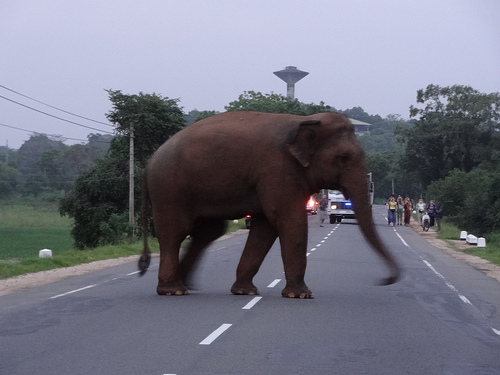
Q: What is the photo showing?
A: It is showing a road.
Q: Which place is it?
A: It is a road.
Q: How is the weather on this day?
A: It is cloudy.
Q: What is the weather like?
A: It is cloudy.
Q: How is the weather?
A: It is cloudy.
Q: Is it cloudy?
A: Yes, it is cloudy.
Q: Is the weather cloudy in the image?
A: Yes, it is cloudy.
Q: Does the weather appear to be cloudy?
A: Yes, it is cloudy.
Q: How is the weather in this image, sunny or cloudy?
A: It is cloudy.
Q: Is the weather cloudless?
A: No, it is cloudy.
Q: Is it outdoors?
A: Yes, it is outdoors.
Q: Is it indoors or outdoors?
A: It is outdoors.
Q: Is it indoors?
A: No, it is outdoors.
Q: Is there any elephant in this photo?
A: Yes, there is an elephant.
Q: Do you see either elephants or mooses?
A: Yes, there is an elephant.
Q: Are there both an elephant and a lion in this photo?
A: No, there is an elephant but no lions.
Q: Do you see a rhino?
A: No, there are no rhinos.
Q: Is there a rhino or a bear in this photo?
A: No, there are no rhinos or bears.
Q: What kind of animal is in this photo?
A: The animal is an elephant.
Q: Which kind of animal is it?
A: The animal is an elephant.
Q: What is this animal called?
A: This is an elephant.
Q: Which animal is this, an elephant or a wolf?
A: This is an elephant.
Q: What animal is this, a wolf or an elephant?
A: This is an elephant.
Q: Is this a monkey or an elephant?
A: This is an elephant.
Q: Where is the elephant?
A: The elephant is on the street.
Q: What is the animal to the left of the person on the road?
A: The animal is an elephant.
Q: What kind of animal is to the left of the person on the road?
A: The animal is an elephant.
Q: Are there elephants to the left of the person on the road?
A: Yes, there is an elephant to the left of the person.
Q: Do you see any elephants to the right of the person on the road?
A: No, the elephant is to the left of the person.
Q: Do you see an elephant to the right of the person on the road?
A: No, the elephant is to the left of the person.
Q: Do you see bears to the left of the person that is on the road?
A: No, there is an elephant to the left of the person.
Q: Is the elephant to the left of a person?
A: Yes, the elephant is to the left of a person.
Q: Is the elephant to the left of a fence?
A: No, the elephant is to the left of a person.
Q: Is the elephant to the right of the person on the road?
A: No, the elephant is to the left of the person.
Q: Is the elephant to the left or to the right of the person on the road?
A: The elephant is to the left of the person.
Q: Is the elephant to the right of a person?
A: No, the elephant is to the left of a person.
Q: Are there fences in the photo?
A: No, there are no fences.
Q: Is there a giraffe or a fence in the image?
A: No, there are no fences or giraffes.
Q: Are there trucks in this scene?
A: Yes, there is a truck.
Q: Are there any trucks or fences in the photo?
A: Yes, there is a truck.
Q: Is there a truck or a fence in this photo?
A: Yes, there is a truck.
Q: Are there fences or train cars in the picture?
A: No, there are no fences or train cars.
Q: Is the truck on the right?
A: Yes, the truck is on the right of the image.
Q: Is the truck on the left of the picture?
A: No, the truck is on the right of the image.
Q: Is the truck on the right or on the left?
A: The truck is on the right of the image.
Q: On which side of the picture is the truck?
A: The truck is on the right of the image.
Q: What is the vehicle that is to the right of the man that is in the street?
A: The vehicle is a truck.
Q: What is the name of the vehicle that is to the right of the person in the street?
A: The vehicle is a truck.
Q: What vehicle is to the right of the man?
A: The vehicle is a truck.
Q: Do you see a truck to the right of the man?
A: Yes, there is a truck to the right of the man.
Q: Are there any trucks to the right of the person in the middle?
A: Yes, there is a truck to the right of the man.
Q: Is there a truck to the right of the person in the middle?
A: Yes, there is a truck to the right of the man.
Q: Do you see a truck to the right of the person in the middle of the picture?
A: Yes, there is a truck to the right of the man.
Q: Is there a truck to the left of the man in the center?
A: No, the truck is to the right of the man.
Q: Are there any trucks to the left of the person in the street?
A: No, the truck is to the right of the man.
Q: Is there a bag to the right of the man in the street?
A: No, there is a truck to the right of the man.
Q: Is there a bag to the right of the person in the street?
A: No, there is a truck to the right of the man.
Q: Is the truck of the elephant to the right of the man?
A: Yes, the truck is to the right of the man.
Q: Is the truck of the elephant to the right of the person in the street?
A: Yes, the truck is to the right of the man.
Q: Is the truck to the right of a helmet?
A: No, the truck is to the right of the man.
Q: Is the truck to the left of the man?
A: No, the truck is to the right of the man.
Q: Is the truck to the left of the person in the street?
A: No, the truck is to the right of the man.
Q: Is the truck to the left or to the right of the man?
A: The truck is to the right of the man.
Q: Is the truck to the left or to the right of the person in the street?
A: The truck is to the right of the man.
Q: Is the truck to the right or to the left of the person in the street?
A: The truck is to the right of the man.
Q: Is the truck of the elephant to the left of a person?
A: Yes, the truck is to the left of a person.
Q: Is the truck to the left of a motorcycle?
A: No, the truck is to the left of a person.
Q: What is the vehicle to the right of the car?
A: The vehicle is a truck.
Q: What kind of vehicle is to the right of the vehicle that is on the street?
A: The vehicle is a truck.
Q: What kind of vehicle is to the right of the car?
A: The vehicle is a truck.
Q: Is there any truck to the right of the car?
A: Yes, there is a truck to the right of the car.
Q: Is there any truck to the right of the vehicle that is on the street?
A: Yes, there is a truck to the right of the car.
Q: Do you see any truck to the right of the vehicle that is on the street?
A: Yes, there is a truck to the right of the car.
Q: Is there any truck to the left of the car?
A: No, the truck is to the right of the car.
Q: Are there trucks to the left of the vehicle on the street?
A: No, the truck is to the right of the car.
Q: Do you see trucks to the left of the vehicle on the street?
A: No, the truck is to the right of the car.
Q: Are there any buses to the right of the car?
A: No, there is a truck to the right of the car.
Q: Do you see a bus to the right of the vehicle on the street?
A: No, there is a truck to the right of the car.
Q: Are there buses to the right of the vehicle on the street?
A: No, there is a truck to the right of the car.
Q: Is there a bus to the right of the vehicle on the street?
A: No, there is a truck to the right of the car.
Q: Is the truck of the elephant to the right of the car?
A: Yes, the truck is to the right of the car.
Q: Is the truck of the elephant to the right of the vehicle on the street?
A: Yes, the truck is to the right of the car.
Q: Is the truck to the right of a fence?
A: No, the truck is to the right of the car.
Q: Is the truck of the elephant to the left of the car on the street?
A: No, the truck is to the right of the car.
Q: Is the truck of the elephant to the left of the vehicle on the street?
A: No, the truck is to the right of the car.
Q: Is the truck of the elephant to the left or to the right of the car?
A: The truck is to the right of the car.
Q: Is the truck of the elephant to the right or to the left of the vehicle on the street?
A: The truck is to the right of the car.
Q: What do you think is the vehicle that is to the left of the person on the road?
A: The vehicle is a truck.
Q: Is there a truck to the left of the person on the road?
A: Yes, there is a truck to the left of the person.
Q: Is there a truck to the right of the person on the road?
A: No, the truck is to the left of the person.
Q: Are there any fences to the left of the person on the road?
A: No, there is a truck to the left of the person.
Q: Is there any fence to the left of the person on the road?
A: No, there is a truck to the left of the person.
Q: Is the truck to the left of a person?
A: Yes, the truck is to the left of a person.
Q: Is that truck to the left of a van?
A: No, the truck is to the left of a person.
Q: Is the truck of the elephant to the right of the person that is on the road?
A: No, the truck is to the left of the person.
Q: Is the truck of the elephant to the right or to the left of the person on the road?
A: The truck is to the left of the person.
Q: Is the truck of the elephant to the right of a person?
A: No, the truck is to the left of a person.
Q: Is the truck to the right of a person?
A: No, the truck is to the left of a person.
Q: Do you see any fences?
A: No, there are no fences.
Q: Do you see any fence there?
A: No, there are no fences.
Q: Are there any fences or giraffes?
A: No, there are no fences or giraffes.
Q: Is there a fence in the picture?
A: No, there are no fences.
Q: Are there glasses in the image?
A: No, there are no glasses.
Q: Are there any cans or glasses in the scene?
A: No, there are no glasses or cans.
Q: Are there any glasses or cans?
A: No, there are no glasses or cans.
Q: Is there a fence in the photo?
A: No, there are no fences.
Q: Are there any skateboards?
A: No, there are no skateboards.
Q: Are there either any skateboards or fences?
A: No, there are no skateboards or fences.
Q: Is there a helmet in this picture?
A: No, there are no helmets.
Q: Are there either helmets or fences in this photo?
A: No, there are no helmets or fences.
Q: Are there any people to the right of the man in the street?
A: Yes, there is a person to the right of the man.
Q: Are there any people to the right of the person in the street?
A: Yes, there is a person to the right of the man.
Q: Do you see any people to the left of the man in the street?
A: No, the person is to the right of the man.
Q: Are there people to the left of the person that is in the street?
A: No, the person is to the right of the man.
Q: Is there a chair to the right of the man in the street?
A: No, there is a person to the right of the man.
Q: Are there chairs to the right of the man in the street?
A: No, there is a person to the right of the man.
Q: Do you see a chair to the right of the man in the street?
A: No, there is a person to the right of the man.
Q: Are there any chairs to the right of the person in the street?
A: No, there is a person to the right of the man.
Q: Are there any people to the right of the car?
A: Yes, there is a person to the right of the car.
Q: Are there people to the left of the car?
A: No, the person is to the right of the car.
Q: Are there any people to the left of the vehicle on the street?
A: No, the person is to the right of the car.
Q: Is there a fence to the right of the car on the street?
A: No, there is a person to the right of the car.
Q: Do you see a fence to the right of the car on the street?
A: No, there is a person to the right of the car.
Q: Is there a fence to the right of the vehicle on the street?
A: No, there is a person to the right of the car.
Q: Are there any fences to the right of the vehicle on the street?
A: No, there is a person to the right of the car.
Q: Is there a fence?
A: No, there are no fences.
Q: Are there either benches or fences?
A: No, there are no fences or benches.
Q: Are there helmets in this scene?
A: No, there are no helmets.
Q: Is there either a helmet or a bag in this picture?
A: No, there are no helmets or bags.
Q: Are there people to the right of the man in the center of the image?
A: Yes, there is a person to the right of the man.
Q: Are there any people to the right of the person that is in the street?
A: Yes, there is a person to the right of the man.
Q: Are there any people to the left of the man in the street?
A: No, the person is to the right of the man.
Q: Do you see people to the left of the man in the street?
A: No, the person is to the right of the man.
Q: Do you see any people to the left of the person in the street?
A: No, the person is to the right of the man.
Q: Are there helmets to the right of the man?
A: No, there is a person to the right of the man.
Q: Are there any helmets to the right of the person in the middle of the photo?
A: No, there is a person to the right of the man.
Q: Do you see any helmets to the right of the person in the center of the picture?
A: No, there is a person to the right of the man.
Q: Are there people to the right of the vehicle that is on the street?
A: Yes, there is a person to the right of the car.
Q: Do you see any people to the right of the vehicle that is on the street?
A: Yes, there is a person to the right of the car.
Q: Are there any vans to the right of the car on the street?
A: No, there is a person to the right of the car.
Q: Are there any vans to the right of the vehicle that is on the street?
A: No, there is a person to the right of the car.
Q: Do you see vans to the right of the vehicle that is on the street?
A: No, there is a person to the right of the car.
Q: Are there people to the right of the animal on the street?
A: Yes, there is a person to the right of the elephant.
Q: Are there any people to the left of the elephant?
A: No, the person is to the right of the elephant.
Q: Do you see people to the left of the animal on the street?
A: No, the person is to the right of the elephant.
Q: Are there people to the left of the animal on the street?
A: No, the person is to the right of the elephant.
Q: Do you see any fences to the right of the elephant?
A: No, there is a person to the right of the elephant.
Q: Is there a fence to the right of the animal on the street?
A: No, there is a person to the right of the elephant.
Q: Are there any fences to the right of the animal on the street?
A: No, there is a person to the right of the elephant.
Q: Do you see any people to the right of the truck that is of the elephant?
A: Yes, there is a person to the right of the truck.